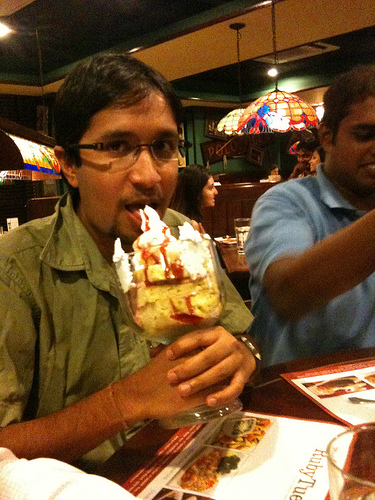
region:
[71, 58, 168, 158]
boy has brown hair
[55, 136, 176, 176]
boy is wearing glasses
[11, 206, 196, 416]
boy has green shirt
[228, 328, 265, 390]
boy has brown watch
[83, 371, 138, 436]
boy is wearing bracelet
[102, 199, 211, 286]
whipped cream on cake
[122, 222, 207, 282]
syrup is on cake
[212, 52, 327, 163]
lamps hanging behind boy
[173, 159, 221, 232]
girl is behind boy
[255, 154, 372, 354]
man has blue shirt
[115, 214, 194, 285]
A delicious looking ice cream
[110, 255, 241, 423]
A glass of delicious looking ice cream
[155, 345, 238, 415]
hands holding a delicious looking ice cream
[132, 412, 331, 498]
the hotel menu with writtings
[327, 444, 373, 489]
An empty glass on the table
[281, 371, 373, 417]
the hotal menu with writtings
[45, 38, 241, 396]
A fat man enjoying icecream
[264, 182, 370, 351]
A man in a blue shirt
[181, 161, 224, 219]
A woman with long black hair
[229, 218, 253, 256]
A glass of drinkiing water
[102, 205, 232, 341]
Man about to eat some dessert.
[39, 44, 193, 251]
Out to eat with some close friends.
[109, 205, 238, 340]
Very large dessert inside a glass.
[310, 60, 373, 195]
Enjoying a meal with friends.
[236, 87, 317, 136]
Lights to illuminate different tables.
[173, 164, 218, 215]
Enjoying dinner and fellowship with friends.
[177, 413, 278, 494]
Featured entrees of a restaurant chain.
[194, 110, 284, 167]
Decorations to make the restaurant exciting.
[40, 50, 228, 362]
Enjoying a birthday celebration with friends.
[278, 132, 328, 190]
Friends enjoying conversation over a nice meal.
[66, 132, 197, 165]
a man's eyeglasses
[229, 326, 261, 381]
part of a man's gray watch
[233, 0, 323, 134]
a long ceiling light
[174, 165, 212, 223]
a woman's black hair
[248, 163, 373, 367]
part of a man's blue shirt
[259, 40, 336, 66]
a white ac vent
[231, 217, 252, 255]
part of a glass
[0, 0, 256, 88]
part of a green wall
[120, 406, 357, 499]
part of a restaurant menu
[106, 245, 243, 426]
a tall glass of dessert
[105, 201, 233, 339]
Ice cream sundae in a large cup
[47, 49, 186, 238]
Man about to enjoy an ice cream sundae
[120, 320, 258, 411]
Two hands holding the bottom of a large cup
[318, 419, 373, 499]
Foreground transparent glass cup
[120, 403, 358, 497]
Paper on table showing the restaurant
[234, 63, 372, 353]
Man in blue shirt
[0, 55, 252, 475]
Man in green shirt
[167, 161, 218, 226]
Woman talking in the backround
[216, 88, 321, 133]
Fancy lamps hanging from ceiling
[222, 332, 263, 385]
Wrist watch around mans wrist